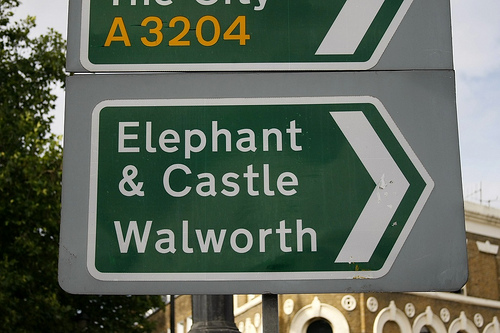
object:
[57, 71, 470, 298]
sign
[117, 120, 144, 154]
letters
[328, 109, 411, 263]
arrow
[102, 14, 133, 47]
letters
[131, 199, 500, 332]
building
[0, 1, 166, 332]
tree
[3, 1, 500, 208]
sky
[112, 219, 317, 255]
words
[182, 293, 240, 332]
pole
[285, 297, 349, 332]
arch